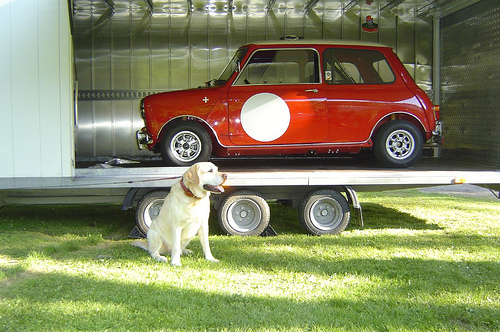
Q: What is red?
A: Car.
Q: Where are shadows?
A: On the grass.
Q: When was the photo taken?
A: Daytime.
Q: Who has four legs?
A: Dog.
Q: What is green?
A: Grass.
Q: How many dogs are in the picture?
A: One.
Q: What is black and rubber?
A: Tires.